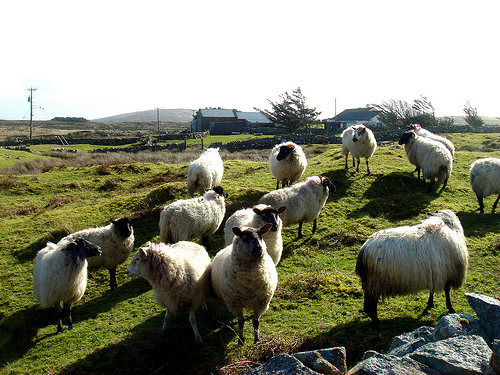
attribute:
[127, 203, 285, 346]
sheep — looking, white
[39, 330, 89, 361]
grass — green, shaded, rich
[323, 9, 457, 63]
sky — white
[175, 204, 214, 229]
fur — white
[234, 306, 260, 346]
legs — black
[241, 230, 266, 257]
face — black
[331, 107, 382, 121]
roof — grey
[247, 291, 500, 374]
rocks — grey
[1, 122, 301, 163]
terrain — uneven